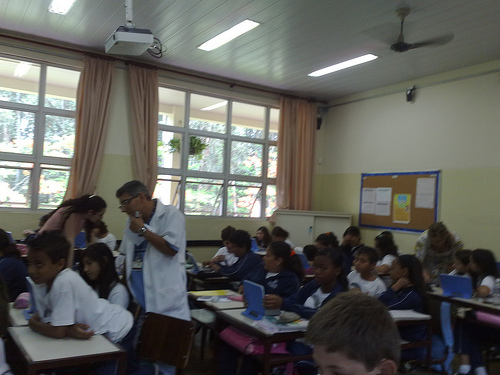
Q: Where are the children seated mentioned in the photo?
A: Near the board.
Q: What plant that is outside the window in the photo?
A: Green hanging plant.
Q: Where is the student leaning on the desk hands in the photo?
A: On the white table.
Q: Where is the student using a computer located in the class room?
A: Student with blue computer.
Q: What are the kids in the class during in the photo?
A: Sitting.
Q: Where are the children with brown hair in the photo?
A: Near the window.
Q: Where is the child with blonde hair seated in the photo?
A: To the right.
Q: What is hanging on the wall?
A: Bulletin Board.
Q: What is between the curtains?
A: Windows.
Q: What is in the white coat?
A: The man.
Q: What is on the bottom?
A: The open windows.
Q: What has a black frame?
A: White desk top.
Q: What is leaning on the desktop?
A: The boy.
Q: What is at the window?
A: Beige drape.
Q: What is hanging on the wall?
A: The bulletin board.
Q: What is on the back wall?
A: A bulletin board.